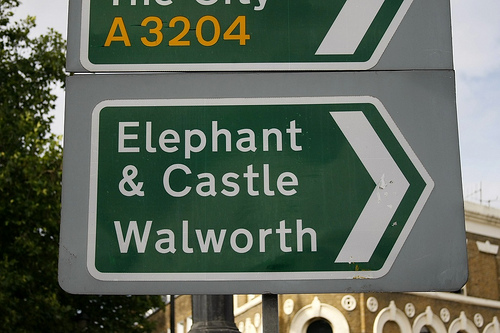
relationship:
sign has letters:
[57, 71, 470, 298] [117, 120, 303, 156]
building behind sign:
[139, 199, 500, 332] [57, 71, 470, 298]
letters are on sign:
[117, 120, 303, 156] [57, 71, 470, 298]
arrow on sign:
[328, 108, 411, 269] [57, 71, 470, 298]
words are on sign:
[112, 163, 323, 257] [57, 71, 470, 298]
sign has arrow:
[57, 71, 470, 298] [328, 108, 411, 269]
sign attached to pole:
[57, 71, 470, 298] [182, 293, 239, 332]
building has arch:
[139, 199, 500, 332] [285, 297, 349, 332]